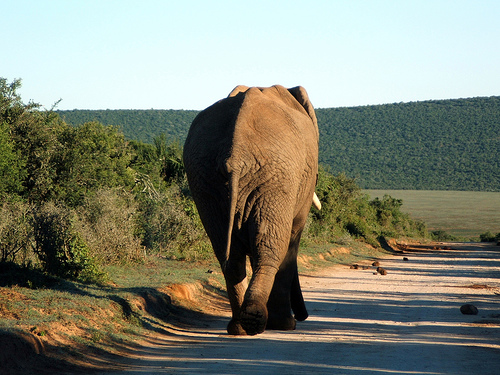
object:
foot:
[237, 298, 270, 335]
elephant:
[182, 83, 323, 333]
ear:
[227, 84, 250, 96]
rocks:
[375, 266, 388, 277]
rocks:
[347, 265, 358, 270]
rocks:
[372, 259, 377, 265]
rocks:
[370, 270, 376, 280]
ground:
[56, 241, 499, 374]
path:
[0, 241, 499, 375]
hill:
[35, 95, 498, 188]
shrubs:
[477, 228, 497, 242]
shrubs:
[24, 199, 109, 286]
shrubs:
[21, 193, 113, 285]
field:
[356, 189, 498, 241]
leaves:
[46, 142, 53, 149]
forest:
[0, 79, 402, 282]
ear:
[286, 86, 317, 138]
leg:
[244, 201, 291, 299]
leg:
[192, 208, 250, 314]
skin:
[248, 119, 296, 140]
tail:
[226, 177, 242, 261]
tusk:
[309, 191, 321, 210]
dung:
[457, 301, 479, 315]